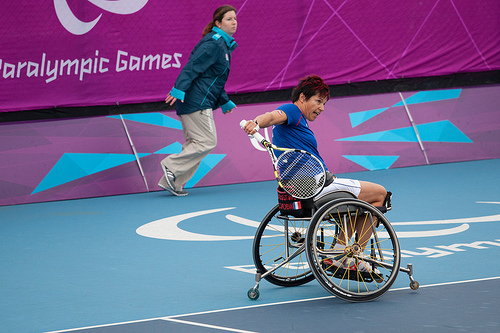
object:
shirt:
[271, 103, 328, 181]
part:
[313, 188, 358, 215]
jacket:
[170, 27, 238, 117]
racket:
[239, 119, 327, 199]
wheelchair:
[247, 178, 419, 301]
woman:
[241, 76, 387, 276]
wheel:
[307, 198, 400, 303]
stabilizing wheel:
[244, 288, 260, 300]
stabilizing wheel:
[409, 280, 421, 290]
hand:
[242, 119, 258, 134]